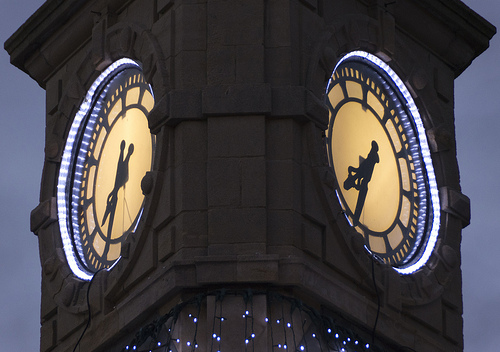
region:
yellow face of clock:
[12, 71, 207, 233]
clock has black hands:
[63, 115, 183, 322]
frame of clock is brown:
[27, 15, 238, 322]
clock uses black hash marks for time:
[72, 96, 169, 262]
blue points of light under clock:
[157, 288, 292, 348]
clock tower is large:
[73, 9, 445, 329]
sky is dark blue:
[9, 125, 35, 242]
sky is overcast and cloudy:
[0, 146, 35, 308]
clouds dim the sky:
[0, 120, 37, 294]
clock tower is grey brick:
[148, 34, 289, 277]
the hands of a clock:
[85, 132, 141, 268]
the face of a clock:
[55, 51, 163, 281]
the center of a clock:
[103, 154, 135, 189]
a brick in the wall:
[201, 201, 273, 249]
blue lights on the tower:
[121, 306, 376, 350]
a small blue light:
[213, 331, 225, 344]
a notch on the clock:
[112, 81, 135, 119]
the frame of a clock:
[27, 12, 179, 323]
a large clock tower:
[2, 0, 497, 350]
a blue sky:
[0, 0, 499, 350]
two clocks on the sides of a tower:
[56, 50, 442, 278]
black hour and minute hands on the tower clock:
[97, 137, 135, 267]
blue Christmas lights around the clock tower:
[100, 288, 375, 350]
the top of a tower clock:
[0, 1, 498, 349]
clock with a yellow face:
[327, 70, 418, 265]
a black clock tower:
[3, 1, 497, 348]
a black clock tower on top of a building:
[5, 1, 496, 349]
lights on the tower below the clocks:
[118, 287, 378, 350]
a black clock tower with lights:
[3, 0, 495, 348]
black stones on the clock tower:
[172, 35, 304, 281]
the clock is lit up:
[286, 24, 459, 283]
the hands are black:
[340, 130, 380, 217]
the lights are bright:
[410, 100, 441, 219]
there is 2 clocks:
[23, 31, 451, 270]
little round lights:
[129, 304, 345, 341]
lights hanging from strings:
[138, 296, 349, 348]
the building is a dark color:
[159, 56, 306, 286]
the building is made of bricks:
[162, 57, 307, 259]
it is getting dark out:
[5, 84, 71, 199]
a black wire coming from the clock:
[335, 243, 402, 330]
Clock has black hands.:
[92, 152, 151, 226]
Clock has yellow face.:
[95, 146, 187, 246]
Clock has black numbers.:
[116, 97, 176, 199]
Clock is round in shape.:
[53, 127, 215, 253]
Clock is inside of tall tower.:
[43, 82, 190, 273]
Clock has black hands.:
[329, 112, 413, 217]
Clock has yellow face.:
[354, 82, 434, 247]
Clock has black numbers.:
[344, 85, 471, 282]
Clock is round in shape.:
[345, 69, 446, 293]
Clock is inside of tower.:
[308, 30, 411, 292]